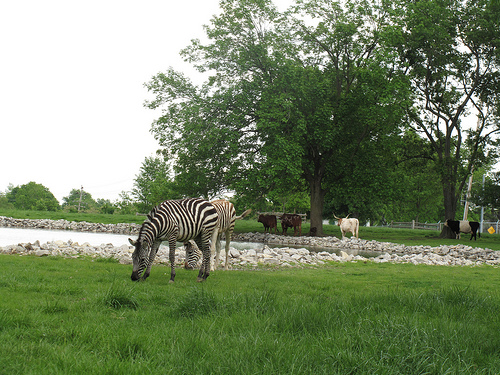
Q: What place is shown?
A: It is a field.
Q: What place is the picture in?
A: It is at the field.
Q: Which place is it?
A: It is a field.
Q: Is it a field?
A: Yes, it is a field.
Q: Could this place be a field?
A: Yes, it is a field.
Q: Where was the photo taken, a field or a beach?
A: It was taken at a field.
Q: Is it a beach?
A: No, it is a field.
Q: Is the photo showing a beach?
A: No, the picture is showing a field.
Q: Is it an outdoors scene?
A: Yes, it is outdoors.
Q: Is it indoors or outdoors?
A: It is outdoors.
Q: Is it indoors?
A: No, it is outdoors.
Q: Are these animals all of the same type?
A: No, there are both zebras and cows.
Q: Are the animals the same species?
A: No, there are both zebras and cows.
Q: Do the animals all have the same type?
A: No, there are both zebras and cows.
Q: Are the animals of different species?
A: Yes, they are zebras and cows.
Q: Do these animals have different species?
A: Yes, they are zebras and cows.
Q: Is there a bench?
A: No, there are no benches.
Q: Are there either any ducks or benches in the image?
A: No, there are no benches or ducks.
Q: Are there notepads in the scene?
A: No, there are no notepads.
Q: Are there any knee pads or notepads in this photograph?
A: No, there are no notepads or knee pads.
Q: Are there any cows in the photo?
A: Yes, there is a cow.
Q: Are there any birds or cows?
A: Yes, there is a cow.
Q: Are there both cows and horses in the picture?
A: No, there is a cow but no horses.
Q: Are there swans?
A: No, there are no swans.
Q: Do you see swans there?
A: No, there are no swans.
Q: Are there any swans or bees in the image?
A: No, there are no swans or bees.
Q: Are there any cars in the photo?
A: No, there are no cars.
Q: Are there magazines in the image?
A: No, there are no magazines.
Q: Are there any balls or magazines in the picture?
A: No, there are no magazines or balls.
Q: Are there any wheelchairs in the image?
A: No, there are no wheelchairs.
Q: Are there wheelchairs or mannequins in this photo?
A: No, there are no wheelchairs or mannequins.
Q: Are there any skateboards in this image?
A: No, there are no skateboards.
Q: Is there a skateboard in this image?
A: No, there are no skateboards.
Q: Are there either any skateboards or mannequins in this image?
A: No, there are no skateboards or mannequins.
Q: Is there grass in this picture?
A: Yes, there is grass.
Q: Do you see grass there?
A: Yes, there is grass.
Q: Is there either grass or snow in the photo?
A: Yes, there is grass.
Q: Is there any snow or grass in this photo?
A: Yes, there is grass.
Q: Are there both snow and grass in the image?
A: No, there is grass but no snow.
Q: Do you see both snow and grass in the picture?
A: No, there is grass but no snow.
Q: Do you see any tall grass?
A: Yes, there is tall grass.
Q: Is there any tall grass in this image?
A: Yes, there is tall grass.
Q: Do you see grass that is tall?
A: Yes, there is grass that is tall.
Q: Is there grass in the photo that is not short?
A: Yes, there is tall grass.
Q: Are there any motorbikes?
A: No, there are no motorbikes.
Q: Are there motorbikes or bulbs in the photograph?
A: No, there are no motorbikes or bulbs.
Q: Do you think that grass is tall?
A: Yes, the grass is tall.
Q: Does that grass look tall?
A: Yes, the grass is tall.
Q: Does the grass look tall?
A: Yes, the grass is tall.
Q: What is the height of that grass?
A: The grass is tall.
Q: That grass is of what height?
A: The grass is tall.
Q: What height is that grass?
A: The grass is tall.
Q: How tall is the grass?
A: The grass is tall.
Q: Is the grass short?
A: No, the grass is tall.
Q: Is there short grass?
A: No, there is grass but it is tall.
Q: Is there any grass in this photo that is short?
A: No, there is grass but it is tall.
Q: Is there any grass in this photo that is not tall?
A: No, there is grass but it is tall.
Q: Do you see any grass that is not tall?
A: No, there is grass but it is tall.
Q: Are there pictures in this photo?
A: No, there are no pictures.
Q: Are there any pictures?
A: No, there are no pictures.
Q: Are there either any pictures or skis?
A: No, there are no pictures or skis.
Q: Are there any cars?
A: No, there are no cars.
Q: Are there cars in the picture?
A: No, there are no cars.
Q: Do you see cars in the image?
A: No, there are no cars.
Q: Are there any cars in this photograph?
A: No, there are no cars.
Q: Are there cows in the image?
A: Yes, there is a cow.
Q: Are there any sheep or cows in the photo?
A: Yes, there is a cow.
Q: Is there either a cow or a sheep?
A: Yes, there is a cow.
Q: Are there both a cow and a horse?
A: No, there is a cow but no horses.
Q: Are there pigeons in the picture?
A: No, there are no pigeons.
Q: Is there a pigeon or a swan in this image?
A: No, there are no pigeons or swans.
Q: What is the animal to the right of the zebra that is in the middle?
A: The animal is a cow.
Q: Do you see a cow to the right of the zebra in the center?
A: Yes, there is a cow to the right of the zebra.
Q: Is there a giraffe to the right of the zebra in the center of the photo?
A: No, there is a cow to the right of the zebra.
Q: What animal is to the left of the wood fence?
A: The animal is a cow.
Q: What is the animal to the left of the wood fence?
A: The animal is a cow.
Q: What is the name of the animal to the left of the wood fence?
A: The animal is a cow.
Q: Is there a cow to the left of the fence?
A: Yes, there is a cow to the left of the fence.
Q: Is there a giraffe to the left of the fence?
A: No, there is a cow to the left of the fence.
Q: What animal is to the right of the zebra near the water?
A: The animal is a cow.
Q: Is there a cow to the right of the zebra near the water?
A: Yes, there is a cow to the right of the zebra.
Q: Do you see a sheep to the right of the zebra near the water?
A: No, there is a cow to the right of the zebra.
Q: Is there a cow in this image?
A: Yes, there is a cow.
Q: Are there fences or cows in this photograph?
A: Yes, there is a cow.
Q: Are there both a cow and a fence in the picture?
A: Yes, there are both a cow and a fence.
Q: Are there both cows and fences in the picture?
A: Yes, there are both a cow and a fence.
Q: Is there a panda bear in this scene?
A: No, there are no panda bears.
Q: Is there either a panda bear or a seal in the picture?
A: No, there are no panda bears or seals.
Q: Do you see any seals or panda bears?
A: No, there are no panda bears or seals.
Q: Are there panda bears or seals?
A: No, there are no panda bears or seals.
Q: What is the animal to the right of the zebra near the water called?
A: The animal is a cow.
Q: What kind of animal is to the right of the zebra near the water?
A: The animal is a cow.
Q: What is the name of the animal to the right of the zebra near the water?
A: The animal is a cow.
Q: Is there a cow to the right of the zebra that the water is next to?
A: Yes, there is a cow to the right of the zebra.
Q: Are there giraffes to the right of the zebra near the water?
A: No, there is a cow to the right of the zebra.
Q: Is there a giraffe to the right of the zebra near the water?
A: No, there is a cow to the right of the zebra.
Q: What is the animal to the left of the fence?
A: The animal is a cow.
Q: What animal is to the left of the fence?
A: The animal is a cow.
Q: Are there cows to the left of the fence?
A: Yes, there is a cow to the left of the fence.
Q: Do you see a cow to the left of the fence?
A: Yes, there is a cow to the left of the fence.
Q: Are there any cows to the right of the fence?
A: No, the cow is to the left of the fence.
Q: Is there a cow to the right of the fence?
A: No, the cow is to the left of the fence.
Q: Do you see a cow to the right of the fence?
A: No, the cow is to the left of the fence.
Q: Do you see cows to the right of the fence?
A: No, the cow is to the left of the fence.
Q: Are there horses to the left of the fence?
A: No, there is a cow to the left of the fence.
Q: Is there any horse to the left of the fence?
A: No, there is a cow to the left of the fence.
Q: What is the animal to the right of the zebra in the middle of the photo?
A: The animal is a cow.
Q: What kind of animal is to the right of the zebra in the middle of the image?
A: The animal is a cow.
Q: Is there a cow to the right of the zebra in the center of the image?
A: Yes, there is a cow to the right of the zebra.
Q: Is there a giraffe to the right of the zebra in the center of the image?
A: No, there is a cow to the right of the zebra.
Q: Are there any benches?
A: No, there are no benches.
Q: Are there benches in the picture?
A: No, there are no benches.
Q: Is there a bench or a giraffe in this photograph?
A: No, there are no benches or giraffes.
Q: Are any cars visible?
A: No, there are no cars.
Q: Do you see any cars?
A: No, there are no cars.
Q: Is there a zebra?
A: Yes, there is a zebra.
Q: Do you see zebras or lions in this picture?
A: Yes, there is a zebra.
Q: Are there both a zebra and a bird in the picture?
A: No, there is a zebra but no birds.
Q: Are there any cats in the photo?
A: No, there are no cats.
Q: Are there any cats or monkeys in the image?
A: No, there are no cats or monkeys.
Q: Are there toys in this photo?
A: No, there are no toys.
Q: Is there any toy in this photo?
A: No, there are no toys.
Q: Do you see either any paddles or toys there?
A: No, there are no toys or paddles.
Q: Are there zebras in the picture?
A: Yes, there is a zebra.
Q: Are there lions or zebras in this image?
A: Yes, there is a zebra.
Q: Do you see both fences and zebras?
A: Yes, there are both a zebra and a fence.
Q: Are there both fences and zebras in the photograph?
A: Yes, there are both a zebra and a fence.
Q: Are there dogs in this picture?
A: No, there are no dogs.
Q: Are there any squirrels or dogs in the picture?
A: No, there are no dogs or squirrels.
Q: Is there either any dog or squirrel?
A: No, there are no dogs or squirrels.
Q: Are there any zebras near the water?
A: Yes, there is a zebra near the water.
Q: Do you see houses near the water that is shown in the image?
A: No, there is a zebra near the water.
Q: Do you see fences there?
A: Yes, there is a fence.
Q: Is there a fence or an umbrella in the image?
A: Yes, there is a fence.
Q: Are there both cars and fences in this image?
A: No, there is a fence but no cars.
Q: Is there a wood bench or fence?
A: Yes, there is a wood fence.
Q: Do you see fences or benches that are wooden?
A: Yes, the fence is wooden.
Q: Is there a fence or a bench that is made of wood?
A: Yes, the fence is made of wood.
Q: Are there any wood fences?
A: Yes, there is a wood fence.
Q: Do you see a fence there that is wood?
A: Yes, there is a wood fence.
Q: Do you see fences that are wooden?
A: Yes, there is a wood fence.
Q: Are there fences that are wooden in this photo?
A: Yes, there is a wood fence.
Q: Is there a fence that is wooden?
A: Yes, there is a fence that is wooden.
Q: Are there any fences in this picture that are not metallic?
A: Yes, there is a wooden fence.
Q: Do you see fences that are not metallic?
A: Yes, there is a wooden fence.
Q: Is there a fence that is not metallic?
A: Yes, there is a wooden fence.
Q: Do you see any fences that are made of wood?
A: Yes, there is a fence that is made of wood.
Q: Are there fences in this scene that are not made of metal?
A: Yes, there is a fence that is made of wood.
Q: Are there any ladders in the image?
A: No, there are no ladders.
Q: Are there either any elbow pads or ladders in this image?
A: No, there are no ladders or elbow pads.